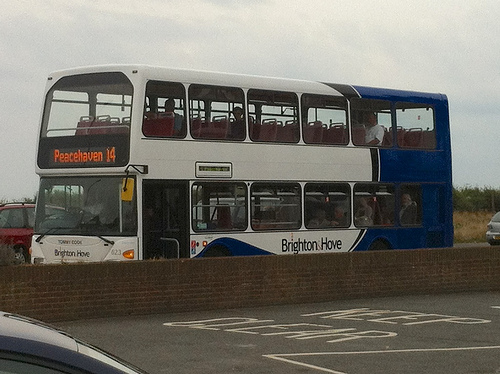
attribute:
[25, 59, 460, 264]
bus — doubledecker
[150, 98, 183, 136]
man — sitting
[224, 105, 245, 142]
woman — sitting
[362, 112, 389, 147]
man — sitting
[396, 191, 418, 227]
man — sitting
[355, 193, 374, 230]
woman — sitting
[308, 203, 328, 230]
woman — sitting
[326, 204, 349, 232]
man — sitting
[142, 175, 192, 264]
door — closed